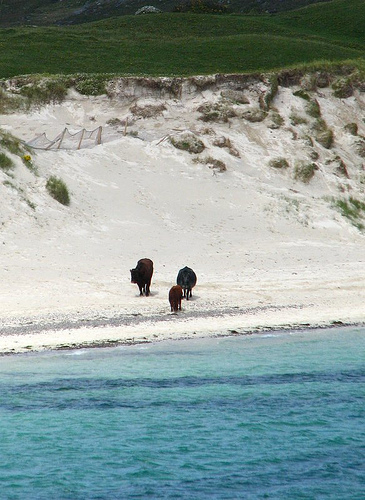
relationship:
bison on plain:
[131, 256, 197, 314] [0, 80, 361, 351]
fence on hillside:
[21, 104, 180, 150] [0, 30, 362, 252]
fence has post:
[21, 104, 180, 150] [24, 129, 42, 146]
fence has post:
[21, 104, 180, 150] [56, 118, 66, 151]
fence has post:
[21, 104, 180, 150] [93, 122, 105, 142]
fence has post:
[21, 104, 180, 150] [73, 123, 86, 151]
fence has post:
[21, 104, 180, 150] [121, 111, 129, 136]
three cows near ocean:
[168, 265, 196, 310] [1, 325, 364, 498]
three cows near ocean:
[130, 259, 198, 312] [1, 325, 364, 498]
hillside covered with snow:
[3, 7, 362, 356] [86, 155, 218, 246]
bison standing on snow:
[130, 257, 154, 296] [163, 224, 236, 245]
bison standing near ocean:
[130, 257, 154, 296] [0, 324, 364, 498]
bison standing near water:
[169, 285, 184, 314] [172, 336, 221, 367]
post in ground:
[78, 128, 85, 151] [1, 59, 363, 354]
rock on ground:
[183, 92, 335, 183] [1, 59, 363, 354]